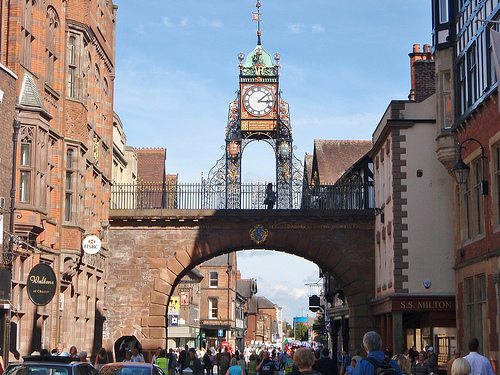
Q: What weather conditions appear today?
A: It is clear.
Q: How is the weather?
A: It is clear.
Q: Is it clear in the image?
A: Yes, it is clear.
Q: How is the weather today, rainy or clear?
A: It is clear.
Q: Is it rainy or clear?
A: It is clear.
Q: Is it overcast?
A: No, it is clear.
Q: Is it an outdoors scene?
A: Yes, it is outdoors.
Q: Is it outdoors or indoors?
A: It is outdoors.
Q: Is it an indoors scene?
A: No, it is outdoors.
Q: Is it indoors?
A: No, it is outdoors.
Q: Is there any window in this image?
A: Yes, there are windows.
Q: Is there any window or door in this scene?
A: Yes, there are windows.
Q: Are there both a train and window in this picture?
A: No, there are windows but no trains.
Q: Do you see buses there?
A: No, there are no buses.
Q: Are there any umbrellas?
A: No, there are no umbrellas.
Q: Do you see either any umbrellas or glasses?
A: No, there are no umbrellas or glasses.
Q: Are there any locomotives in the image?
A: No, there are no locomotives.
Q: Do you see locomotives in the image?
A: No, there are no locomotives.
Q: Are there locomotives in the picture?
A: No, there are no locomotives.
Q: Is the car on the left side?
A: Yes, the car is on the left of the image.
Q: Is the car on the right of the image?
A: No, the car is on the left of the image.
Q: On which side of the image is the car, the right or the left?
A: The car is on the left of the image.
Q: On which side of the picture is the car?
A: The car is on the left of the image.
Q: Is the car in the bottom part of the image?
A: Yes, the car is in the bottom of the image.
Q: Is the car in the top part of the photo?
A: No, the car is in the bottom of the image.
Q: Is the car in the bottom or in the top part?
A: The car is in the bottom of the image.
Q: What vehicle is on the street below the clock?
A: The vehicle is a car.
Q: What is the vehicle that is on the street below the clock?
A: The vehicle is a car.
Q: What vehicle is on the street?
A: The vehicle is a car.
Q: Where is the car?
A: The car is on the street.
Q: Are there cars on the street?
A: Yes, there is a car on the street.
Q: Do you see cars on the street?
A: Yes, there is a car on the street.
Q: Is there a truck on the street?
A: No, there is a car on the street.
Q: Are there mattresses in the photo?
A: No, there are no mattresses.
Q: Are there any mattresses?
A: No, there are no mattresses.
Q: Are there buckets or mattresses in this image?
A: No, there are no mattresses or buckets.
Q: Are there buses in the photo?
A: No, there are no buses.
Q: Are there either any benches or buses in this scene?
A: No, there are no buses or benches.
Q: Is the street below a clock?
A: Yes, the street is below a clock.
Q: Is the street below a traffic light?
A: No, the street is below a clock.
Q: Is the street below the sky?
A: Yes, the street is below the sky.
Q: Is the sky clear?
A: Yes, the sky is clear.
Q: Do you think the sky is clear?
A: Yes, the sky is clear.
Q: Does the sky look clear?
A: Yes, the sky is clear.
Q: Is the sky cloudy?
A: No, the sky is clear.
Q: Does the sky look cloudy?
A: No, the sky is clear.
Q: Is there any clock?
A: Yes, there is a clock.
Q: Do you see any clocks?
A: Yes, there is a clock.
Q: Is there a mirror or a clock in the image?
A: Yes, there is a clock.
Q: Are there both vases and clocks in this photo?
A: No, there is a clock but no vases.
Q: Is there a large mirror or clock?
A: Yes, there is a large clock.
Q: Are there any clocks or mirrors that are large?
A: Yes, the clock is large.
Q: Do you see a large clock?
A: Yes, there is a large clock.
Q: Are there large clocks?
A: Yes, there is a large clock.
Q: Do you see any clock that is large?
A: Yes, there is a clock that is large.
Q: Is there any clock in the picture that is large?
A: Yes, there is a clock that is large.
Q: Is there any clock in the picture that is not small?
A: Yes, there is a large clock.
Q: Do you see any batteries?
A: No, there are no batteries.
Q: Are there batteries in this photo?
A: No, there are no batteries.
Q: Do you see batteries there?
A: No, there are no batteries.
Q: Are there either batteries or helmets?
A: No, there are no batteries or helmets.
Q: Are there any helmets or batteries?
A: No, there are no batteries or helmets.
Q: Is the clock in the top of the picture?
A: Yes, the clock is in the top of the image.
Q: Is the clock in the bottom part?
A: No, the clock is in the top of the image.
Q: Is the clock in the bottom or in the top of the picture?
A: The clock is in the top of the image.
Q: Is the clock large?
A: Yes, the clock is large.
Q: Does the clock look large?
A: Yes, the clock is large.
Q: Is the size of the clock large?
A: Yes, the clock is large.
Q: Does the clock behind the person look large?
A: Yes, the clock is large.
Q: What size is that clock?
A: The clock is large.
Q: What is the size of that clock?
A: The clock is large.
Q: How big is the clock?
A: The clock is large.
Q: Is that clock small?
A: No, the clock is large.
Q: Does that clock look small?
A: No, the clock is large.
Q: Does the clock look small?
A: No, the clock is large.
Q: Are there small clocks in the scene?
A: No, there is a clock but it is large.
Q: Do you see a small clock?
A: No, there is a clock but it is large.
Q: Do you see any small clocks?
A: No, there is a clock but it is large.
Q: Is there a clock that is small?
A: No, there is a clock but it is large.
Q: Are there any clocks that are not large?
A: No, there is a clock but it is large.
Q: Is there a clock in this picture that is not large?
A: No, there is a clock but it is large.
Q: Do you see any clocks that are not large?
A: No, there is a clock but it is large.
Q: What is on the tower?
A: The clock is on the tower.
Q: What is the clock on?
A: The clock is on the tower.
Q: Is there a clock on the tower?
A: Yes, there is a clock on the tower.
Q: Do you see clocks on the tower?
A: Yes, there is a clock on the tower.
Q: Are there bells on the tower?
A: No, there is a clock on the tower.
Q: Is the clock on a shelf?
A: No, the clock is on a tower.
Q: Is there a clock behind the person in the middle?
A: Yes, there is a clock behind the person.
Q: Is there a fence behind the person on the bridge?
A: No, there is a clock behind the person.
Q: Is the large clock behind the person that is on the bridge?
A: Yes, the clock is behind the person.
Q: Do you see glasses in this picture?
A: No, there are no glasses.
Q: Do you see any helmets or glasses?
A: No, there are no glasses or helmets.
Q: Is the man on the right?
A: Yes, the man is on the right of the image.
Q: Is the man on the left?
A: No, the man is on the right of the image.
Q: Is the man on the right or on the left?
A: The man is on the right of the image.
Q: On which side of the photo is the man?
A: The man is on the right of the image.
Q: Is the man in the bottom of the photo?
A: Yes, the man is in the bottom of the image.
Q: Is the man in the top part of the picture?
A: No, the man is in the bottom of the image.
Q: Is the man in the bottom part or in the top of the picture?
A: The man is in the bottom of the image.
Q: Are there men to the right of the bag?
A: Yes, there is a man to the right of the bag.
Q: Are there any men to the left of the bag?
A: No, the man is to the right of the bag.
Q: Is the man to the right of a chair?
A: No, the man is to the right of the bag.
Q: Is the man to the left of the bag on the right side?
A: No, the man is to the right of the bag.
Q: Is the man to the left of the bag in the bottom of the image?
A: No, the man is to the right of the bag.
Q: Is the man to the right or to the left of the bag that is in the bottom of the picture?
A: The man is to the right of the bag.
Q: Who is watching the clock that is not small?
A: The man is watching the clock.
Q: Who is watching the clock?
A: The man is watching the clock.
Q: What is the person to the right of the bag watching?
A: The man is watching the clock.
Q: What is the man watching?
A: The man is watching the clock.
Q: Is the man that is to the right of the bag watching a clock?
A: Yes, the man is watching a clock.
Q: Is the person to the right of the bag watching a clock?
A: Yes, the man is watching a clock.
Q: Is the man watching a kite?
A: No, the man is watching a clock.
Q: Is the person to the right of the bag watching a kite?
A: No, the man is watching a clock.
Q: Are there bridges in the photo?
A: Yes, there is a bridge.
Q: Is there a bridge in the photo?
A: Yes, there is a bridge.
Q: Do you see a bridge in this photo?
A: Yes, there is a bridge.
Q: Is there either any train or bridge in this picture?
A: Yes, there is a bridge.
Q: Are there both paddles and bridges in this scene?
A: No, there is a bridge but no paddles.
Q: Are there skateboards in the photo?
A: No, there are no skateboards.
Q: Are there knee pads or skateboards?
A: No, there are no skateboards or knee pads.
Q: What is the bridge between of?
A: The bridge is between the buildings.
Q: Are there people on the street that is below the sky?
A: Yes, there are people on the street.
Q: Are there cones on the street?
A: No, there are people on the street.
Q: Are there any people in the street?
A: Yes, there are people in the street.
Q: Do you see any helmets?
A: No, there are no helmets.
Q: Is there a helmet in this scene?
A: No, there are no helmets.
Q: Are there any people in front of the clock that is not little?
A: Yes, there is a person in front of the clock.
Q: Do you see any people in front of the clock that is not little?
A: Yes, there is a person in front of the clock.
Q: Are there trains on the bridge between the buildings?
A: No, there is a person on the bridge.